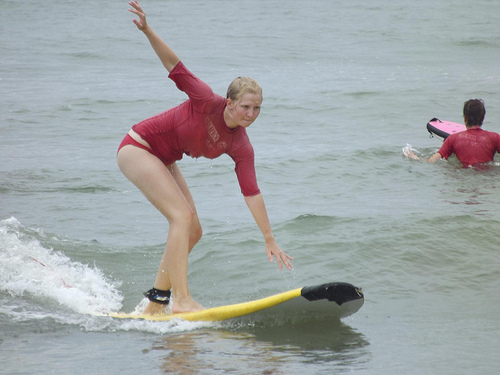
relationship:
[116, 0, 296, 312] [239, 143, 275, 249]
girl extending arm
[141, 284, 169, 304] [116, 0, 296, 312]
ankle tie on girl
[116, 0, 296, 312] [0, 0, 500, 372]
girl in water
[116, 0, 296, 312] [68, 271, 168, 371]
girl in water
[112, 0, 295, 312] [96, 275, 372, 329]
girl balancing on surfboard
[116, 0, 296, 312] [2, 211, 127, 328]
girl riding waves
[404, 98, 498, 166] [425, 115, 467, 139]
surfer with pink surfboard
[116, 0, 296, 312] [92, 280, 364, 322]
girl on surfboard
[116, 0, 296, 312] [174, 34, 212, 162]
girl wearing red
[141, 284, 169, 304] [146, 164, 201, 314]
ankle tie on suffers leg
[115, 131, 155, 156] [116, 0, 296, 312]
bathing suit bottom of girl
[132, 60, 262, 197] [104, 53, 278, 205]
bathing suit of surfers bathing suit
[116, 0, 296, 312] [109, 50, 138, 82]
girl raised arm in air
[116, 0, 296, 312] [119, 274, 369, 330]
girl riding surfboard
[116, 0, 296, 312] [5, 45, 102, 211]
girl in ocean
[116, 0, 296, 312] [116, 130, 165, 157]
girl wearing bikini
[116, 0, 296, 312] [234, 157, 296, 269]
girl has arm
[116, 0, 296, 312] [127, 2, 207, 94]
girl has arm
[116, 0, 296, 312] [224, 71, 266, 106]
girl with blonde hair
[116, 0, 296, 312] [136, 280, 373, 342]
girl standing on surfboard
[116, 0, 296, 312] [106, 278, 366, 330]
girl on surfboard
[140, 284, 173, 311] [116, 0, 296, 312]
ankle tie on girl